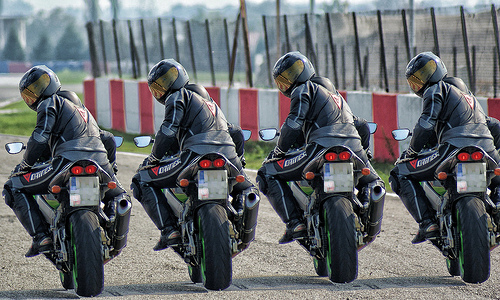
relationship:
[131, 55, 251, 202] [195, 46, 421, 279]
man on motorcycle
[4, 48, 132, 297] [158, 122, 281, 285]
man on motorcycle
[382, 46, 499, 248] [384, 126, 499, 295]
man on motorcycle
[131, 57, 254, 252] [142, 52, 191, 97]
man wearing helmet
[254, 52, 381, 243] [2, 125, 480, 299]
man on motorcycles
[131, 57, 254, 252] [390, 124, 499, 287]
man on motorcycle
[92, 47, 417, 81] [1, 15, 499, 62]
fence on background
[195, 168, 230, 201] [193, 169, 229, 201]
place on license plate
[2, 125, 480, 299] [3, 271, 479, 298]
motorcycles has shadows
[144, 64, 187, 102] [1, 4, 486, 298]
helmet in photo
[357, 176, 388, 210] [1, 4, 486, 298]
pipe in photo